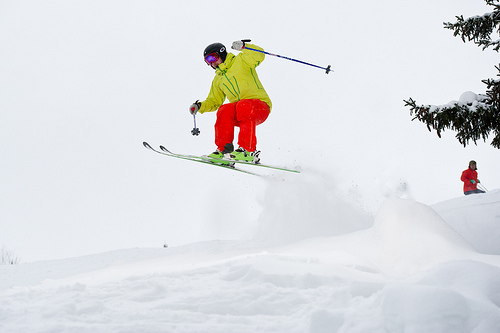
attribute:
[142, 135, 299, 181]
skis — green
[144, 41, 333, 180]
skier — jumping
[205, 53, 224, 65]
goggles — red, purple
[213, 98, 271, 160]
orange — bent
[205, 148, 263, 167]
boots — lime-green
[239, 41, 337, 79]
pole — black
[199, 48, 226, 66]
goggles — red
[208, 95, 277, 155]
pants — neon orange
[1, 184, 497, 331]
snow — white